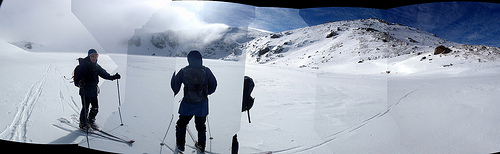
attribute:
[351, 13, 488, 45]
sky — blue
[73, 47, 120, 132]
man — skiing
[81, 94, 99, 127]
pants — dark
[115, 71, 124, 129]
stick — for propelling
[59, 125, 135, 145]
skis — white, a set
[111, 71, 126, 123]
poles — for skiing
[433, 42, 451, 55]
rock — bare, black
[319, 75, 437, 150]
tracks — longer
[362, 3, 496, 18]
sky — bright, blue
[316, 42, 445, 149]
snow — white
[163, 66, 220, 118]
jacket — blue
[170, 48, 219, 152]
man — skiing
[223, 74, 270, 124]
back pack — blue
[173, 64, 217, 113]
jacket — blue